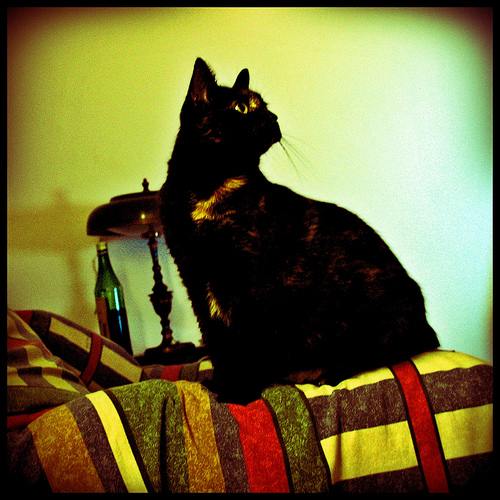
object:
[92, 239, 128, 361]
glass bottle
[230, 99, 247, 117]
eye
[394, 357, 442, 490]
stripes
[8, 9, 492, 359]
wall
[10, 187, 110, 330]
shadow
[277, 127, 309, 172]
whiskers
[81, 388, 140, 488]
stripes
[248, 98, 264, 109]
eye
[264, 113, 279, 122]
nose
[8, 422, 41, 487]
stripes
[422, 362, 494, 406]
stripes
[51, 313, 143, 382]
stripes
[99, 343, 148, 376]
stripes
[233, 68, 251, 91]
ear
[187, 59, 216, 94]
ear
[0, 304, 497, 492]
chair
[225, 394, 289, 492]
stripes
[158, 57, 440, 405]
black cat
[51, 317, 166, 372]
diagonal stripe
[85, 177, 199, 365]
lamp base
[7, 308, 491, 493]
blanket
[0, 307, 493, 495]
quilt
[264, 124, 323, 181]
whiskers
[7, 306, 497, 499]
couch